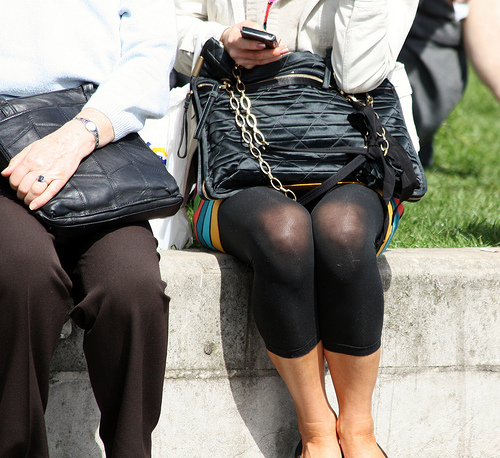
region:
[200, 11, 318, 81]
woman is holding phone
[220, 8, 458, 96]
woman has white shirt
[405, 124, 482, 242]
green grass behind woman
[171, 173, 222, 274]
woman has rainbow skirt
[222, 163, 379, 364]
woman has black leggings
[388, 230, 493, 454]
woman sits on concrete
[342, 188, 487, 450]
concrete is light grey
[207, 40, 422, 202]
woman holds black bag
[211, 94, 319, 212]
gold chain on bag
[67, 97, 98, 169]
woman is wearing watch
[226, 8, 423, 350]
this is a lady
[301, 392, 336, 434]
the lady is light skinned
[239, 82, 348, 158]
this is a bag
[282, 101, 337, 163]
the bag is black in color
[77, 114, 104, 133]
this is a watch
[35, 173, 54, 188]
this is a ring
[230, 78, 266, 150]
this is a chain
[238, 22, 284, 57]
this is a phone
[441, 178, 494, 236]
this is a grass area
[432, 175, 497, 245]
the grass is green in color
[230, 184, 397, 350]
black leggings on woman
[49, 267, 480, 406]
concrete wall beneath people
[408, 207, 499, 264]
grass growing behind field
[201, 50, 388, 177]
black purse on woman's lap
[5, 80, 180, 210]
black purse on woman's lap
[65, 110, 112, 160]
wrist watch on woman's arm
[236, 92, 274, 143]
chains hanging on purse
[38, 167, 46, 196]
small ring on woman's finger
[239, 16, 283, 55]
cell phone in hand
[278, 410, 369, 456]
slip on shoes on woman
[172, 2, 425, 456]
Woman sitting on wall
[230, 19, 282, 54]
Phone in the woman's hand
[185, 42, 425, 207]
Purse on woman's lap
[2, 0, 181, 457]
Woman sitting on wall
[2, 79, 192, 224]
Purse on woman's lap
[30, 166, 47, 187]
Ring on woman's finger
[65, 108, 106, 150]
Watch on woman's wrist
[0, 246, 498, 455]
Stone wall under women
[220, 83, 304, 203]
Chain strap on purse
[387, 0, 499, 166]
Person sitting on grass in background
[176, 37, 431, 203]
black purse with chain accent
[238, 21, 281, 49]
black cell phone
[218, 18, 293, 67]
black cell phone in woman's hand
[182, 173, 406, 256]
skirt with colorful stripes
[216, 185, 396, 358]
black footless tights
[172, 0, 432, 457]
woman in white shirt looking at her cell phone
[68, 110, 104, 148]
silver watch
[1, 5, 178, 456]
woman in white shirt and brown pants holding her purse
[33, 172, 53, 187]
gold ring on woman's ring finger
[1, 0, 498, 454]
two women sitting on a wall